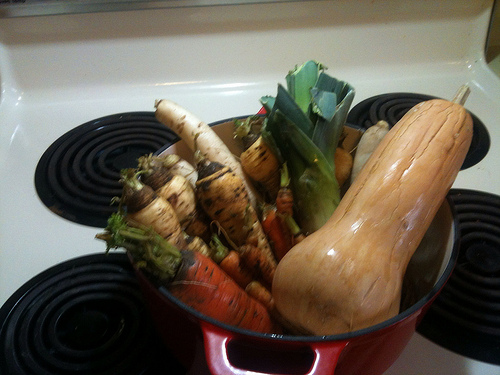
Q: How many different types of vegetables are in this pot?
A: Four.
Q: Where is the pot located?
A: On the stove.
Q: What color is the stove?
A: Black and white.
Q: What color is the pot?
A: Red.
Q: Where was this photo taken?
A: A kitchen.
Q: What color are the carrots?
A: Orange.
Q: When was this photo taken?
A: Before cooking food.